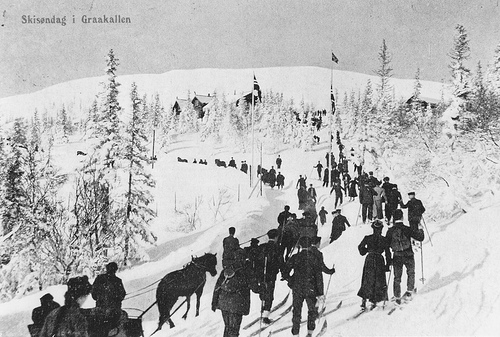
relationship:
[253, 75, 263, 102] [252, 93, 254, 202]
flag on pole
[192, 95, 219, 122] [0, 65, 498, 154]
house on hill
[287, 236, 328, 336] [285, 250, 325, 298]
person wearing black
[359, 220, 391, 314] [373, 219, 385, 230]
lady wearing hat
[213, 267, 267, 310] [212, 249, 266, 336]
coat on person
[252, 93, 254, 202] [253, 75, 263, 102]
pole has flag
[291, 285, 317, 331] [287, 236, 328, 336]
trousers on person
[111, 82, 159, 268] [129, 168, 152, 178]
tree has branches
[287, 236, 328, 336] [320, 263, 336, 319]
person holding stick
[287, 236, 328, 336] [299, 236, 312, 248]
person wearing hat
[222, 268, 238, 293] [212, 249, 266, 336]
bag on person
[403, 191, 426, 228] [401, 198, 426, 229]
person wearing suit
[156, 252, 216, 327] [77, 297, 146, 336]
horse towing sleigh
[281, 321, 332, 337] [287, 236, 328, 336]
skis on person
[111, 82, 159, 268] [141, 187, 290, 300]
tree near path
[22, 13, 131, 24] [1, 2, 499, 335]
label on photo